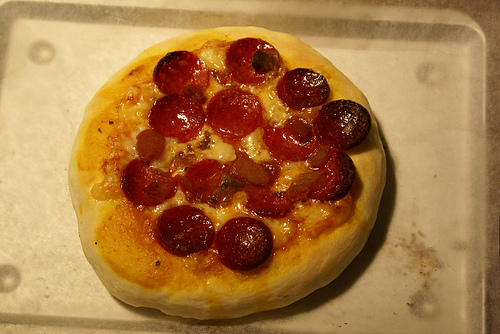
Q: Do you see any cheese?
A: Yes, there is cheese.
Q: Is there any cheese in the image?
A: Yes, there is cheese.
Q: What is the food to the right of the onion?
A: The food is cheese.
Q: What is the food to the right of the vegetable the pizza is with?
A: The food is cheese.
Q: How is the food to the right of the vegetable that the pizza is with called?
A: The food is cheese.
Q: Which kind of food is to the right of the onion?
A: The food is cheese.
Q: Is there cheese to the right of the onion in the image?
A: Yes, there is cheese to the right of the onion.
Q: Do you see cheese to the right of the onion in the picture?
A: Yes, there is cheese to the right of the onion.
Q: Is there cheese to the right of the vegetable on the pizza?
A: Yes, there is cheese to the right of the onion.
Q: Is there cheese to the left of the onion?
A: No, the cheese is to the right of the onion.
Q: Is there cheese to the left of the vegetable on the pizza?
A: No, the cheese is to the right of the onion.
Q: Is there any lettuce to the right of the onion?
A: No, there is cheese to the right of the onion.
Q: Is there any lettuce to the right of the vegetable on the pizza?
A: No, there is cheese to the right of the onion.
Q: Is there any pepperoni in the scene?
A: Yes, there is pepperoni.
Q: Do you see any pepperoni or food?
A: Yes, there is pepperoni.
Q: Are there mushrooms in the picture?
A: No, there are no mushrooms.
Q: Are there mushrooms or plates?
A: No, there are no mushrooms or plates.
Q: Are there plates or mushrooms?
A: No, there are no mushrooms or plates.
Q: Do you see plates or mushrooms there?
A: No, there are no mushrooms or plates.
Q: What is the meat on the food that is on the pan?
A: The meat is pepperoni.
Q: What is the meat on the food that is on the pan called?
A: The meat is pepperoni.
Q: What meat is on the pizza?
A: The meat is pepperoni.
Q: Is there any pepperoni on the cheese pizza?
A: Yes, there is pepperoni on the pizza.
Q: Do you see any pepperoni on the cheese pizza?
A: Yes, there is pepperoni on the pizza.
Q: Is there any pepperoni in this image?
A: Yes, there is pepperoni.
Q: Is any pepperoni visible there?
A: Yes, there is pepperoni.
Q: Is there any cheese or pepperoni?
A: Yes, there is pepperoni.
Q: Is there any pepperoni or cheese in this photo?
A: Yes, there is pepperoni.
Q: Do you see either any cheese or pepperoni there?
A: Yes, there is pepperoni.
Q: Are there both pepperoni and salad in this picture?
A: No, there is pepperoni but no salad.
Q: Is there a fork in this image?
A: No, there are no forks.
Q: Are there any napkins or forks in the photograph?
A: No, there are no forks or napkins.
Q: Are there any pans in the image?
A: Yes, there is a pan.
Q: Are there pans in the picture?
A: Yes, there is a pan.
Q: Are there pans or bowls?
A: Yes, there is a pan.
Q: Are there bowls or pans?
A: Yes, there is a pan.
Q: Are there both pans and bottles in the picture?
A: No, there is a pan but no bottles.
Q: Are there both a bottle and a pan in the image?
A: No, there is a pan but no bottles.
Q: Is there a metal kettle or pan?
A: Yes, there is a metal pan.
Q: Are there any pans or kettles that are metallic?
A: Yes, the pan is metallic.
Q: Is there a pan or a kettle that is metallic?
A: Yes, the pan is metallic.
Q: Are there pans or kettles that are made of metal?
A: Yes, the pan is made of metal.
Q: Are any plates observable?
A: No, there are no plates.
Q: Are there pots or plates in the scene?
A: No, there are no plates or pots.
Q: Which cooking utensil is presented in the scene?
A: The cooking utensil is a pan.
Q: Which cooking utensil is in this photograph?
A: The cooking utensil is a pan.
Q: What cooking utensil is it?
A: The cooking utensil is a pan.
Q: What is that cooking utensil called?
A: This is a pan.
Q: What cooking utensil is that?
A: This is a pan.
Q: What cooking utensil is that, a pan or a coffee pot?
A: This is a pan.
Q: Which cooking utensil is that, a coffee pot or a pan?
A: This is a pan.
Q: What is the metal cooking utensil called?
A: The cooking utensil is a pan.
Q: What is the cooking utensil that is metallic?
A: The cooking utensil is a pan.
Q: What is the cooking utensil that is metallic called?
A: The cooking utensil is a pan.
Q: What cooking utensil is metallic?
A: The cooking utensil is a pan.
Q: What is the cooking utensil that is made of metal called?
A: The cooking utensil is a pan.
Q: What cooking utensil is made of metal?
A: The cooking utensil is a pan.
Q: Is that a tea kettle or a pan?
A: That is a pan.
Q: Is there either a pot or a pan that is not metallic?
A: No, there is a pan but it is metallic.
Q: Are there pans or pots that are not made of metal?
A: No, there is a pan but it is made of metal.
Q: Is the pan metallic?
A: Yes, the pan is metallic.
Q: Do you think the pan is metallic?
A: Yes, the pan is metallic.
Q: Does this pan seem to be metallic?
A: Yes, the pan is metallic.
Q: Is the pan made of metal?
A: Yes, the pan is made of metal.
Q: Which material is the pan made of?
A: The pan is made of metal.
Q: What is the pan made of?
A: The pan is made of metal.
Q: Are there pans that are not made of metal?
A: No, there is a pan but it is made of metal.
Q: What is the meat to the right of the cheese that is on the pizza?
A: The meat is pepperoni.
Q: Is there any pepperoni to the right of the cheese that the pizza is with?
A: Yes, there is pepperoni to the right of the cheese.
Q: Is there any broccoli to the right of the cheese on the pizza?
A: No, there is pepperoni to the right of the cheese.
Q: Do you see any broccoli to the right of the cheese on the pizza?
A: No, there is pepperoni to the right of the cheese.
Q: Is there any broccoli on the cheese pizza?
A: No, there is pepperoni on the pizza.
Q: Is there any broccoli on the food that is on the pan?
A: No, there is pepperoni on the pizza.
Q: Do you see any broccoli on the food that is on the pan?
A: No, there is pepperoni on the pizza.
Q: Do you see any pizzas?
A: Yes, there is a pizza.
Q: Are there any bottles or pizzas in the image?
A: Yes, there is a pizza.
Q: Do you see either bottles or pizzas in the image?
A: Yes, there is a pizza.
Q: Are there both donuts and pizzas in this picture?
A: No, there is a pizza but no donuts.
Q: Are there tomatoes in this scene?
A: No, there are no tomatoes.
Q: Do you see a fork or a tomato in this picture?
A: No, there are no tomatoes or forks.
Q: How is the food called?
A: The food is a pizza.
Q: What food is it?
A: The food is a pizza.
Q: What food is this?
A: This is a pizza.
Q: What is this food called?
A: This is a pizza.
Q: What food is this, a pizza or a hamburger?
A: This is a pizza.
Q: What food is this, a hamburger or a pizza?
A: This is a pizza.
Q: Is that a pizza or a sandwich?
A: That is a pizza.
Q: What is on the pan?
A: The pizza is on the pan.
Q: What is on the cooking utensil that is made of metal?
A: The pizza is on the pan.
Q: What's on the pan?
A: The pizza is on the pan.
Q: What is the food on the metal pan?
A: The food is a pizza.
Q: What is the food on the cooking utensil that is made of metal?
A: The food is a pizza.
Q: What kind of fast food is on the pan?
A: The food is a pizza.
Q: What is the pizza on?
A: The pizza is on the pan.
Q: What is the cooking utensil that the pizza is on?
A: The cooking utensil is a pan.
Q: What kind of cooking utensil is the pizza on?
A: The pizza is on the pan.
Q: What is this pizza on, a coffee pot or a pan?
A: The pizza is on a pan.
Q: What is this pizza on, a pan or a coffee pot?
A: The pizza is on a pan.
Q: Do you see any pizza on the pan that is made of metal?
A: Yes, there is a pizza on the pan.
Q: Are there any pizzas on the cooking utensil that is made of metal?
A: Yes, there is a pizza on the pan.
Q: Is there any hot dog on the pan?
A: No, there is a pizza on the pan.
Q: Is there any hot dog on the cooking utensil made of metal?
A: No, there is a pizza on the pan.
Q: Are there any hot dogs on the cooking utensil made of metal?
A: No, there is a pizza on the pan.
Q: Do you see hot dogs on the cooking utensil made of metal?
A: No, there is a pizza on the pan.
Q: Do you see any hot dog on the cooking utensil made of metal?
A: No, there is a pizza on the pan.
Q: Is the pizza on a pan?
A: Yes, the pizza is on a pan.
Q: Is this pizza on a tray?
A: No, the pizza is on a pan.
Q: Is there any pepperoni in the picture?
A: Yes, there is pepperoni.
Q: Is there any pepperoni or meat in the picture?
A: Yes, there is pepperoni.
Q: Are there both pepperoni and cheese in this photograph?
A: Yes, there are both pepperoni and cheese.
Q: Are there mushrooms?
A: No, there are no mushrooms.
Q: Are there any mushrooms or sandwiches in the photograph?
A: No, there are no mushrooms or sandwiches.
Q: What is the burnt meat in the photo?
A: The meat is pepperoni.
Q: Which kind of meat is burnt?
A: The meat is pepperoni.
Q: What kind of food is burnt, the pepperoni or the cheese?
A: The pepperoni is burnt.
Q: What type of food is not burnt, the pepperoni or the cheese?
A: The cheese is not burnt.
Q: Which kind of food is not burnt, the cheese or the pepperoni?
A: The cheese is not burnt.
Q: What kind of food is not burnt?
A: The food is cheese.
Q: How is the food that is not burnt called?
A: The food is cheese.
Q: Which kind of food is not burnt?
A: The food is cheese.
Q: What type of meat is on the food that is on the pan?
A: The meat is pepperoni.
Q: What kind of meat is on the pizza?
A: The meat is pepperoni.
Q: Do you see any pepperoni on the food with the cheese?
A: Yes, there is pepperoni on the pizza.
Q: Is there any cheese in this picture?
A: Yes, there is cheese.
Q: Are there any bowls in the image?
A: No, there are no bowls.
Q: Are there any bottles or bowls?
A: No, there are no bowls or bottles.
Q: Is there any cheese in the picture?
A: Yes, there is cheese.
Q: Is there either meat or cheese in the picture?
A: Yes, there is cheese.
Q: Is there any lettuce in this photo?
A: No, there is no lettuce.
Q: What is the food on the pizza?
A: The food is cheese.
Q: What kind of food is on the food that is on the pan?
A: The food is cheese.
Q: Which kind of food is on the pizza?
A: The food is cheese.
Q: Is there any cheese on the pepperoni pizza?
A: Yes, there is cheese on the pizza.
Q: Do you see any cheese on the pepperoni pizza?
A: Yes, there is cheese on the pizza.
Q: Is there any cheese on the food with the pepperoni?
A: Yes, there is cheese on the pizza.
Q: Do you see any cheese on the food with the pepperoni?
A: Yes, there is cheese on the pizza.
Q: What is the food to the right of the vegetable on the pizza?
A: The food is cheese.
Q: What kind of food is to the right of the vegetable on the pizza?
A: The food is cheese.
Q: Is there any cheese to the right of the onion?
A: Yes, there is cheese to the right of the onion.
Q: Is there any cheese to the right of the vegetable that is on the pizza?
A: Yes, there is cheese to the right of the onion.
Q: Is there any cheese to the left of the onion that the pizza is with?
A: No, the cheese is to the right of the onion.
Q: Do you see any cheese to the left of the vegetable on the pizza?
A: No, the cheese is to the right of the onion.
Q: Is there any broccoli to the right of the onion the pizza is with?
A: No, there is cheese to the right of the onion.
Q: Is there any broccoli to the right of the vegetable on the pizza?
A: No, there is cheese to the right of the onion.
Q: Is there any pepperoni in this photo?
A: Yes, there is pepperoni.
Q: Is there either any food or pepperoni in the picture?
A: Yes, there is pepperoni.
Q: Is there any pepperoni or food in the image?
A: Yes, there is pepperoni.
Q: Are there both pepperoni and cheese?
A: Yes, there are both pepperoni and cheese.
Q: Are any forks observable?
A: No, there are no forks.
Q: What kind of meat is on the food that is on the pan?
A: The meat is pepperoni.